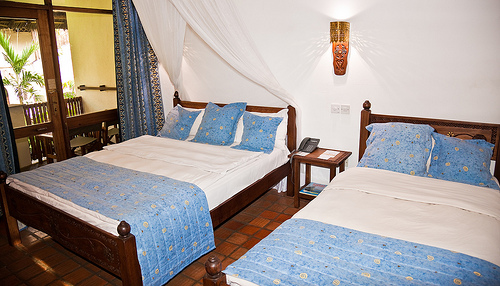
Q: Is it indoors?
A: Yes, it is indoors.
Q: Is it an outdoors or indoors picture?
A: It is indoors.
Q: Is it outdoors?
A: No, it is indoors.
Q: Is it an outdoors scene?
A: No, it is indoors.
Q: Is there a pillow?
A: Yes, there are pillows.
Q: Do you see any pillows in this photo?
A: Yes, there are pillows.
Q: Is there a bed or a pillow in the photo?
A: Yes, there are pillows.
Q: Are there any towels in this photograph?
A: No, there are no towels.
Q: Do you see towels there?
A: No, there are no towels.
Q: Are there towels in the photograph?
A: No, there are no towels.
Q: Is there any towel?
A: No, there are no towels.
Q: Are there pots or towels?
A: No, there are no towels or pots.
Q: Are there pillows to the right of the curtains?
A: Yes, there are pillows to the right of the curtains.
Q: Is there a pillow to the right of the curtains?
A: Yes, there are pillows to the right of the curtains.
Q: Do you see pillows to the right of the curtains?
A: Yes, there are pillows to the right of the curtains.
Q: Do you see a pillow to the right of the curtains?
A: Yes, there are pillows to the right of the curtains.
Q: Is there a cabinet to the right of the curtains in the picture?
A: No, there are pillows to the right of the curtains.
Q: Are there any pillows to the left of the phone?
A: Yes, there are pillows to the left of the phone.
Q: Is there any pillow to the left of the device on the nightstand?
A: Yes, there are pillows to the left of the phone.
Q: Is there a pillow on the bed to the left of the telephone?
A: Yes, there are pillows on the bed.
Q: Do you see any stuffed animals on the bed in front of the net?
A: No, there are pillows on the bed.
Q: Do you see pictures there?
A: No, there are no pictures.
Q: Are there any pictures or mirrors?
A: No, there are no pictures or mirrors.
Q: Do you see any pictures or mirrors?
A: No, there are no pictures or mirrors.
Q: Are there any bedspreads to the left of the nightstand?
A: Yes, there is a bedspread to the left of the nightstand.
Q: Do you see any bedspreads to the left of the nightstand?
A: Yes, there is a bedspread to the left of the nightstand.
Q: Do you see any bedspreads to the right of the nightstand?
A: No, the bedspread is to the left of the nightstand.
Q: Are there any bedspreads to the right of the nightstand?
A: No, the bedspread is to the left of the nightstand.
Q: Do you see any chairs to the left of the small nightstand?
A: No, there is a bedspread to the left of the nightstand.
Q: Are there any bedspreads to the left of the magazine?
A: Yes, there is a bedspread to the left of the magazine.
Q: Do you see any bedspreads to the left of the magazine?
A: Yes, there is a bedspread to the left of the magazine.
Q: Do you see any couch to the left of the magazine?
A: No, there is a bedspread to the left of the magazine.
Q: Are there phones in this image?
A: Yes, there is a phone.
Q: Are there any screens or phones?
A: Yes, there is a phone.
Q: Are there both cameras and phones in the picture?
A: No, there is a phone but no cameras.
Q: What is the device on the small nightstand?
A: The device is a phone.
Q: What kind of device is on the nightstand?
A: The device is a phone.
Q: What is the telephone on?
A: The telephone is on the nightstand.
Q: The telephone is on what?
A: The telephone is on the nightstand.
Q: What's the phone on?
A: The telephone is on the nightstand.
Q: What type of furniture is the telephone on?
A: The telephone is on the nightstand.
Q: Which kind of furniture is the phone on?
A: The telephone is on the nightstand.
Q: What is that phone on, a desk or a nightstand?
A: The phone is on a nightstand.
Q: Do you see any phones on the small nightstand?
A: Yes, there is a phone on the nightstand.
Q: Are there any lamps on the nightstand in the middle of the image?
A: No, there is a phone on the nightstand.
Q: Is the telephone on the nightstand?
A: Yes, the telephone is on the nightstand.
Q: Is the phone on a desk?
A: No, the phone is on the nightstand.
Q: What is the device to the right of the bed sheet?
A: The device is a phone.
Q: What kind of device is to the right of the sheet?
A: The device is a phone.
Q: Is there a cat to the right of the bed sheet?
A: No, there is a phone to the right of the bed sheet.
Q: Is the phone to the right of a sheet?
A: Yes, the phone is to the right of a sheet.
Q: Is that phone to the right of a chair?
A: No, the phone is to the right of a sheet.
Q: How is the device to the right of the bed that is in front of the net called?
A: The device is a phone.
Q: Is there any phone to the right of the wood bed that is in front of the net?
A: Yes, there is a phone to the right of the bed.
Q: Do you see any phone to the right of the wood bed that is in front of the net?
A: Yes, there is a phone to the right of the bed.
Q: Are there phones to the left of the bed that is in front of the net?
A: No, the phone is to the right of the bed.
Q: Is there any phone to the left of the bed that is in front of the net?
A: No, the phone is to the right of the bed.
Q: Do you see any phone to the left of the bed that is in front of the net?
A: No, the phone is to the right of the bed.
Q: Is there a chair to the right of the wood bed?
A: No, there is a phone to the right of the bed.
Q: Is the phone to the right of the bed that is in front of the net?
A: Yes, the phone is to the right of the bed.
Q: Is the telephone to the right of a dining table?
A: No, the telephone is to the right of the bed.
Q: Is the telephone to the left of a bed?
A: No, the telephone is to the right of a bed.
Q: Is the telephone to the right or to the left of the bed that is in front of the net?
A: The telephone is to the right of the bed.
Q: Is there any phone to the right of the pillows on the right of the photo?
A: No, the phone is to the left of the pillows.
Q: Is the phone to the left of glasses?
A: No, the phone is to the left of the pillows.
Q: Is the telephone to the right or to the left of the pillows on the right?
A: The telephone is to the left of the pillows.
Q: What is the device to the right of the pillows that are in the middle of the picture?
A: The device is a phone.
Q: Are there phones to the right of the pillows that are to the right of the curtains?
A: Yes, there is a phone to the right of the pillows.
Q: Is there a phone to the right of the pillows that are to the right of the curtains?
A: Yes, there is a phone to the right of the pillows.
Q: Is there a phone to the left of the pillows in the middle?
A: No, the phone is to the right of the pillows.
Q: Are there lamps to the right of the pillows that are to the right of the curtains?
A: No, there is a phone to the right of the pillows.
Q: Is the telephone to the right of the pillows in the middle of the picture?
A: Yes, the telephone is to the right of the pillows.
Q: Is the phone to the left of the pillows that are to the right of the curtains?
A: No, the phone is to the right of the pillows.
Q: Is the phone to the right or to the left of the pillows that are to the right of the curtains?
A: The phone is to the right of the pillows.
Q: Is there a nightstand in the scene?
A: Yes, there is a nightstand.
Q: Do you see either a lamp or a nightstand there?
A: Yes, there is a nightstand.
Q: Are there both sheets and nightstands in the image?
A: Yes, there are both a nightstand and a sheet.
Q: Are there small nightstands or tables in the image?
A: Yes, there is a small nightstand.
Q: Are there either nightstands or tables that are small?
A: Yes, the nightstand is small.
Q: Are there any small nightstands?
A: Yes, there is a small nightstand.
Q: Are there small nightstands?
A: Yes, there is a small nightstand.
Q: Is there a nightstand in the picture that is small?
A: Yes, there is a nightstand that is small.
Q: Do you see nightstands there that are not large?
A: Yes, there is a small nightstand.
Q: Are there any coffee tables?
A: No, there are no coffee tables.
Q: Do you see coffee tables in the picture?
A: No, there are no coffee tables.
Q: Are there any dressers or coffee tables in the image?
A: No, there are no coffee tables or dressers.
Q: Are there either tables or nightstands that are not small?
A: No, there is a nightstand but it is small.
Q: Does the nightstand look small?
A: Yes, the nightstand is small.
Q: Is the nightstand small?
A: Yes, the nightstand is small.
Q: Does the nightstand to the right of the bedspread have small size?
A: Yes, the nightstand is small.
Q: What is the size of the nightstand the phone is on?
A: The nightstand is small.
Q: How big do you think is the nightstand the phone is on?
A: The nightstand is small.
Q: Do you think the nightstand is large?
A: No, the nightstand is small.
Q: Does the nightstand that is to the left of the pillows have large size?
A: No, the nightstand is small.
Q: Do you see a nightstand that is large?
A: No, there is a nightstand but it is small.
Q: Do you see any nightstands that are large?
A: No, there is a nightstand but it is small.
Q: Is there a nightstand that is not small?
A: No, there is a nightstand but it is small.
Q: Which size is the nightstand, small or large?
A: The nightstand is small.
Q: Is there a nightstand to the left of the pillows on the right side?
A: Yes, there is a nightstand to the left of the pillows.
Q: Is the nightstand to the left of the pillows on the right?
A: Yes, the nightstand is to the left of the pillows.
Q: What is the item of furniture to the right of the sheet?
A: The piece of furniture is a nightstand.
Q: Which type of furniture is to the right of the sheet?
A: The piece of furniture is a nightstand.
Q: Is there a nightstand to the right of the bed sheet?
A: Yes, there is a nightstand to the right of the bed sheet.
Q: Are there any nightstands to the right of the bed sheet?
A: Yes, there is a nightstand to the right of the bed sheet.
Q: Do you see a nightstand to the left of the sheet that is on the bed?
A: No, the nightstand is to the right of the sheet.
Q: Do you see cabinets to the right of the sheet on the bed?
A: No, there is a nightstand to the right of the bed sheet.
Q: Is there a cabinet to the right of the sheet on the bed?
A: No, there is a nightstand to the right of the bed sheet.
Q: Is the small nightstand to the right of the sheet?
A: Yes, the nightstand is to the right of the sheet.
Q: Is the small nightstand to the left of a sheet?
A: No, the nightstand is to the right of a sheet.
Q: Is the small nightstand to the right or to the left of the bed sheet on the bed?
A: The nightstand is to the right of the bed sheet.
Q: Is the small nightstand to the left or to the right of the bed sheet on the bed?
A: The nightstand is to the right of the bed sheet.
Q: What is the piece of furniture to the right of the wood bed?
A: The piece of furniture is a nightstand.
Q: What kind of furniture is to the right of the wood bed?
A: The piece of furniture is a nightstand.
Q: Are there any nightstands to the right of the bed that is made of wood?
A: Yes, there is a nightstand to the right of the bed.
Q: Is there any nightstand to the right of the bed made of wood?
A: Yes, there is a nightstand to the right of the bed.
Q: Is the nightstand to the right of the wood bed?
A: Yes, the nightstand is to the right of the bed.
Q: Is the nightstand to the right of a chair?
A: No, the nightstand is to the right of the bed.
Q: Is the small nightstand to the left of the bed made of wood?
A: No, the nightstand is to the right of the bed.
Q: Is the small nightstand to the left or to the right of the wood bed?
A: The nightstand is to the right of the bed.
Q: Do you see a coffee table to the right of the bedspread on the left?
A: No, there is a nightstand to the right of the bedspread.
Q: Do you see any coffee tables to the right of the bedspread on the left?
A: No, there is a nightstand to the right of the bedspread.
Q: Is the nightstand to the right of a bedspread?
A: Yes, the nightstand is to the right of a bedspread.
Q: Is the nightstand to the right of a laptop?
A: No, the nightstand is to the right of a bedspread.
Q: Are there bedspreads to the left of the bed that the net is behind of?
A: No, the bedspread is to the right of the bed.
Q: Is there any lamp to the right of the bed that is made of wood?
A: No, there is a bedspread to the right of the bed.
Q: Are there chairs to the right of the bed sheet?
A: No, there is a magazine to the right of the bed sheet.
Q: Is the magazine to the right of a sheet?
A: Yes, the magazine is to the right of a sheet.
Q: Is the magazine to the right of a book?
A: No, the magazine is to the right of a sheet.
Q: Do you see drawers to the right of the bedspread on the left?
A: No, there is a magazine to the right of the bedspread.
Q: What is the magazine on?
A: The magazine is on the nightstand.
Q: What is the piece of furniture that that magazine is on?
A: The piece of furniture is a nightstand.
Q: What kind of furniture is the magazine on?
A: The magazine is on the nightstand.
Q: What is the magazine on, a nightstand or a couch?
A: The magazine is on a nightstand.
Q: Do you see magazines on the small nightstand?
A: Yes, there is a magazine on the nightstand.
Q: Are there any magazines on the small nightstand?
A: Yes, there is a magazine on the nightstand.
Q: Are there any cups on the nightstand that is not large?
A: No, there is a magazine on the nightstand.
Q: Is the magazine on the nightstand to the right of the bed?
A: Yes, the magazine is on the nightstand.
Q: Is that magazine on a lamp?
A: No, the magazine is on the nightstand.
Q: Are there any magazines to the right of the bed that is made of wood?
A: Yes, there is a magazine to the right of the bed.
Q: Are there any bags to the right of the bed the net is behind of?
A: No, there is a magazine to the right of the bed.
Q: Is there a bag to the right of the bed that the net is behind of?
A: No, there is a magazine to the right of the bed.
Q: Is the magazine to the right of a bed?
A: Yes, the magazine is to the right of a bed.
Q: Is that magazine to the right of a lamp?
A: No, the magazine is to the right of a bed.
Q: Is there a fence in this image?
A: No, there are no fences.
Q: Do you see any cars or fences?
A: No, there are no fences or cars.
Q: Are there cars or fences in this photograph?
A: No, there are no fences or cars.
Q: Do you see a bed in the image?
A: Yes, there is a bed.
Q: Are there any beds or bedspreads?
A: Yes, there is a bed.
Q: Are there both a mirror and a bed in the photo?
A: No, there is a bed but no mirrors.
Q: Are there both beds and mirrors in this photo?
A: No, there is a bed but no mirrors.